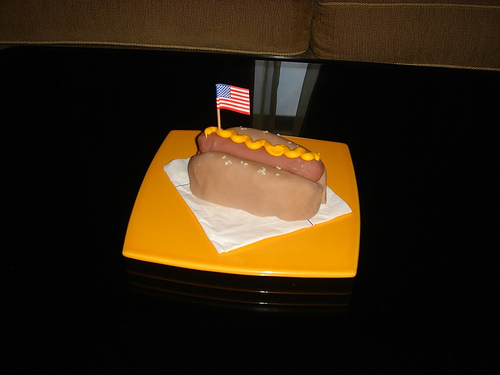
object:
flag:
[215, 83, 250, 117]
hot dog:
[195, 127, 325, 182]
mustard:
[204, 126, 321, 162]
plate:
[121, 128, 361, 279]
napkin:
[162, 156, 353, 255]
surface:
[1, 43, 499, 374]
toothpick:
[216, 110, 221, 131]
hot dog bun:
[188, 150, 329, 223]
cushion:
[0, 1, 315, 59]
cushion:
[310, 0, 500, 73]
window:
[249, 58, 322, 137]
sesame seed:
[275, 172, 280, 178]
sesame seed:
[243, 162, 247, 165]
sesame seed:
[221, 156, 226, 159]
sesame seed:
[276, 133, 280, 137]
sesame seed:
[287, 141, 292, 146]